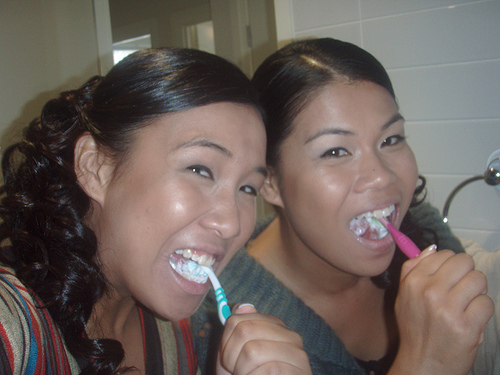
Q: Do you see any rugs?
A: No, there are no rugs.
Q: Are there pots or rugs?
A: No, there are no rugs or pots.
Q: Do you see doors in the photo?
A: Yes, there is a door.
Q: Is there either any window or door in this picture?
A: Yes, there is a door.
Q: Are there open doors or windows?
A: Yes, there is an open door.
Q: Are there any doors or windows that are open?
A: Yes, the door is open.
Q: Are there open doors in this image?
A: Yes, there is an open door.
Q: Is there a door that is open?
A: Yes, there is a door that is open.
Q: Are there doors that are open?
A: Yes, there is a door that is open.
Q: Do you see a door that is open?
A: Yes, there is a door that is open.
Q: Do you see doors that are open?
A: Yes, there is a door that is open.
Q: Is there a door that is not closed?
A: Yes, there is a open door.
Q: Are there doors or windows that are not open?
A: No, there is a door but it is open.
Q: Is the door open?
A: Yes, the door is open.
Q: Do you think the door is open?
A: Yes, the door is open.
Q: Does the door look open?
A: Yes, the door is open.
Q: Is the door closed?
A: No, the door is open.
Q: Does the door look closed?
A: No, the door is open.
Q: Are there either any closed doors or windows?
A: No, there is a door but it is open.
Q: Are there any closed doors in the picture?
A: No, there is a door but it is open.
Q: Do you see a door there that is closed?
A: No, there is a door but it is open.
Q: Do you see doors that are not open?
A: No, there is a door but it is open.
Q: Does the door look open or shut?
A: The door is open.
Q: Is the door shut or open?
A: The door is open.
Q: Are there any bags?
A: No, there are no bags.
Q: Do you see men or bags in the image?
A: No, there are no bags or men.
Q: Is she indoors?
A: Yes, the girl is indoors.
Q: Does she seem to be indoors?
A: Yes, the girl is indoors.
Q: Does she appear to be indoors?
A: Yes, the girl is indoors.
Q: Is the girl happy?
A: Yes, the girl is happy.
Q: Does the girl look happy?
A: Yes, the girl is happy.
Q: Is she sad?
A: No, the girl is happy.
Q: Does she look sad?
A: No, the girl is happy.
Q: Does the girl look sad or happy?
A: The girl is happy.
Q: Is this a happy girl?
A: Yes, this is a happy girl.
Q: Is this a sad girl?
A: No, this is a happy girl.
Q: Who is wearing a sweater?
A: The girl is wearing a sweater.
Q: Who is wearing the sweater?
A: The girl is wearing a sweater.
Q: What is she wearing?
A: The girl is wearing a sweater.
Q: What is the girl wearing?
A: The girl is wearing a sweater.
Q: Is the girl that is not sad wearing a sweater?
A: Yes, the girl is wearing a sweater.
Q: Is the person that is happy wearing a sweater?
A: Yes, the girl is wearing a sweater.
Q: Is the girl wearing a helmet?
A: No, the girl is wearing a sweater.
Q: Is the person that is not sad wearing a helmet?
A: No, the girl is wearing a sweater.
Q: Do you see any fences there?
A: No, there are no fences.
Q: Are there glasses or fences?
A: No, there are no fences or glasses.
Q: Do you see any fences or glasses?
A: No, there are no fences or glasses.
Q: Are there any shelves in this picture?
A: No, there are no shelves.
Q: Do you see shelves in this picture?
A: No, there are no shelves.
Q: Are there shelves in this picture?
A: No, there are no shelves.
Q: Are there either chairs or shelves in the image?
A: No, there are no shelves or chairs.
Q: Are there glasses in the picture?
A: No, there are no glasses.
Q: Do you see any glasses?
A: No, there are no glasses.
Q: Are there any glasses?
A: No, there are no glasses.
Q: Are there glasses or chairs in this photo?
A: No, there are no glasses or chairs.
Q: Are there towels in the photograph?
A: Yes, there is a towel.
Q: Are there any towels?
A: Yes, there is a towel.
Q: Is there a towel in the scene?
A: Yes, there is a towel.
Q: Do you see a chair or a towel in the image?
A: Yes, there is a towel.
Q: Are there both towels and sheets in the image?
A: No, there is a towel but no sheets.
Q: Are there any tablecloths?
A: No, there are no tablecloths.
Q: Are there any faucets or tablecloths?
A: No, there are no tablecloths or faucets.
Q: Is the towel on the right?
A: Yes, the towel is on the right of the image.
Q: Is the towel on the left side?
A: No, the towel is on the right of the image.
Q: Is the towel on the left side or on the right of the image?
A: The towel is on the right of the image.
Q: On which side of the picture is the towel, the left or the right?
A: The towel is on the right of the image.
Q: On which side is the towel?
A: The towel is on the right of the image.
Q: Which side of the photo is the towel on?
A: The towel is on the right of the image.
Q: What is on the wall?
A: The towel is on the wall.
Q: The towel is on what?
A: The towel is on the wall.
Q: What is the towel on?
A: The towel is on the wall.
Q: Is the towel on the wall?
A: Yes, the towel is on the wall.